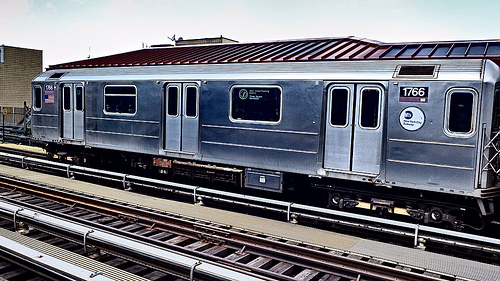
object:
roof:
[42, 36, 500, 73]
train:
[16, 35, 499, 225]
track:
[1, 160, 384, 280]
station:
[0, 33, 500, 279]